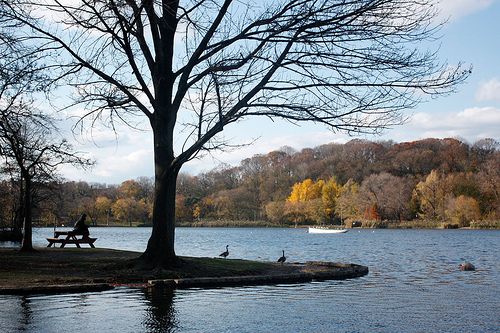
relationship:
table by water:
[47, 230, 99, 250] [102, 224, 499, 269]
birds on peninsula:
[219, 244, 287, 266] [184, 254, 372, 288]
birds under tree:
[219, 244, 287, 266] [3, 4, 468, 263]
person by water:
[73, 211, 95, 228] [102, 224, 499, 269]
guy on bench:
[73, 211, 95, 228] [47, 230, 99, 250]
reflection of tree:
[138, 287, 193, 332] [3, 4, 468, 263]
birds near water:
[214, 242, 290, 261] [102, 224, 499, 269]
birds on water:
[355, 226, 379, 234] [102, 224, 499, 269]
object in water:
[455, 257, 477, 271] [102, 224, 499, 269]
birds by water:
[219, 244, 287, 266] [102, 224, 499, 269]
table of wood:
[47, 230, 99, 250] [60, 240, 76, 245]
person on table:
[73, 211, 95, 228] [47, 230, 99, 250]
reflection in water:
[138, 287, 193, 332] [102, 224, 499, 269]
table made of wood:
[47, 230, 99, 250] [60, 240, 76, 245]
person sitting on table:
[73, 211, 95, 228] [47, 230, 99, 250]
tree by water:
[3, 4, 468, 263] [102, 224, 499, 269]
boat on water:
[301, 225, 349, 235] [102, 224, 499, 269]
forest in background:
[0, 138, 498, 224] [0, 133, 498, 230]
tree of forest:
[285, 178, 323, 204] [0, 138, 498, 224]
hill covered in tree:
[229, 137, 496, 223] [285, 178, 323, 204]